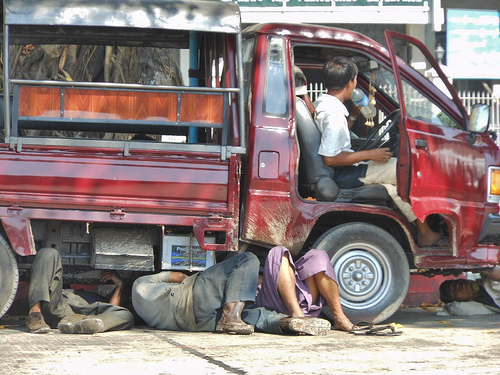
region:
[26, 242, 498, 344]
group of people working on the truck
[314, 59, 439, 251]
man sitting in the driver's seat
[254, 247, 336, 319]
purple pants on the man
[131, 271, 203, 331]
gray shirt on the man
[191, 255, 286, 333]
blue jeans on the man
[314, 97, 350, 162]
white shirt on the man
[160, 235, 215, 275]
car battery under the truck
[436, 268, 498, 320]
man under the front of the car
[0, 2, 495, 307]
red truck parked on the street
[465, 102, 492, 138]
mirror on the side of the truck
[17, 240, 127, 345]
Person laying on the ground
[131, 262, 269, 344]
Person laying on the ground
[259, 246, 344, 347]
Person laying on the ground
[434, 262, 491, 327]
Person laying on the ground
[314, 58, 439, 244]
PErson sitting in the cab of a truck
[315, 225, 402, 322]
Black wheel of a truck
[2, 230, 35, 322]
Black wheel of a truck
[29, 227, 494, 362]
People laying under a truck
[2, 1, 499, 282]
Large red truck with person inside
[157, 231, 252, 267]
White battery under a trucjk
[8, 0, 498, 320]
red truck with an open cap top on the bed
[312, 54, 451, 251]
man sitting in truck with white pants and shirt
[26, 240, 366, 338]
three people part way under the truck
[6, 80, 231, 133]
wood panel in a metal frame on back of truck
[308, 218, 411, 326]
front right wheel of a red truck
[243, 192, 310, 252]
mud splashed behind the wheel of the truck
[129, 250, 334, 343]
man with brown boots, blue pants and a tan shirt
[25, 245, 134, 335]
man with dark gray pants and brown shoes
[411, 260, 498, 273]
rusted portion of the red truck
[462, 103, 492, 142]
right side view mirror on a red truck